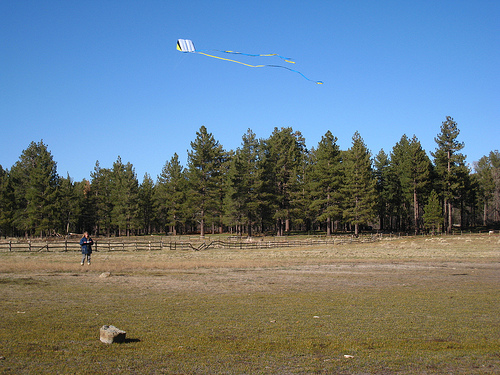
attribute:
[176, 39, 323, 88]
kite — flying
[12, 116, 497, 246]
tree — evergreen 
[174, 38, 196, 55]
kite — colorful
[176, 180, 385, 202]
tree — evergreen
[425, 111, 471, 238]
tree — tall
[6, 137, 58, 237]
green tree — tall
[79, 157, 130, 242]
tree — evergreen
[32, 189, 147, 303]
person — flying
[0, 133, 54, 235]
tree — evergreen 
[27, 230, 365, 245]
fence — behind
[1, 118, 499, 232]
trees — green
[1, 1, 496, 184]
sky — clear, blue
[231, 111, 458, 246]
trees — dark green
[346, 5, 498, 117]
sky — blue , clear 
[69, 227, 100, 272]
woman — flying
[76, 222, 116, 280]
man — standing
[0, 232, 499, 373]
field — green , grassy , dry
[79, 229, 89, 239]
hair — long